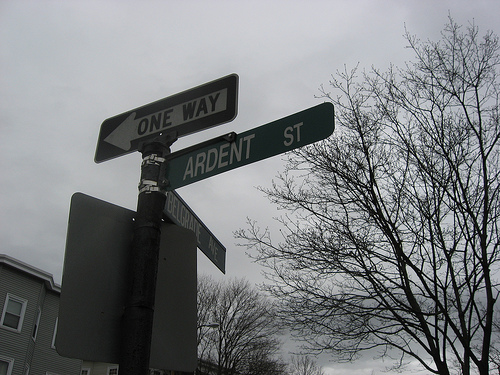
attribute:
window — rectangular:
[3, 295, 22, 329]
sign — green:
[139, 133, 380, 185]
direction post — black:
[89, 71, 240, 162]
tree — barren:
[320, 72, 482, 223]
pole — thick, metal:
[133, 151, 170, 362]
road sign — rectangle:
[62, 193, 196, 368]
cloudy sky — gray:
[0, 0, 498, 372]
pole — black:
[108, 123, 180, 374]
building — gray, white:
[0, 250, 240, 374]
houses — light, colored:
[3, 256, 205, 372]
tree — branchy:
[370, 91, 480, 229]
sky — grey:
[131, 9, 232, 57]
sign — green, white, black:
[93, 73, 237, 163]